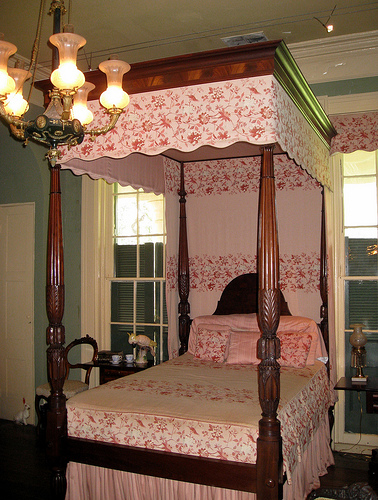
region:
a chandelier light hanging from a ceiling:
[0, 2, 140, 170]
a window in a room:
[340, 126, 373, 438]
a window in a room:
[99, 178, 172, 366]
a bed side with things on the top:
[91, 329, 160, 378]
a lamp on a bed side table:
[328, 319, 374, 398]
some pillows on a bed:
[194, 319, 309, 372]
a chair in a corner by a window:
[32, 325, 98, 434]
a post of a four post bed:
[246, 139, 286, 484]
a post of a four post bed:
[38, 156, 74, 492]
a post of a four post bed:
[174, 156, 195, 356]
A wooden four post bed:
[28, 35, 334, 497]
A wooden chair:
[31, 332, 99, 430]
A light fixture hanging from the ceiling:
[0, 1, 131, 168]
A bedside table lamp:
[347, 324, 370, 387]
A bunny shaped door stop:
[11, 395, 32, 430]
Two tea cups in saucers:
[107, 352, 136, 364]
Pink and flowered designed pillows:
[184, 312, 328, 368]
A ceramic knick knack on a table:
[127, 330, 158, 366]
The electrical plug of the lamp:
[338, 391, 375, 469]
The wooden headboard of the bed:
[215, 269, 299, 314]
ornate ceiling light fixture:
[3, 31, 128, 150]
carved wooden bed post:
[245, 135, 300, 499]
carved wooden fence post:
[43, 147, 78, 436]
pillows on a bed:
[190, 321, 309, 369]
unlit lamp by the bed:
[340, 310, 372, 391]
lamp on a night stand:
[342, 305, 372, 398]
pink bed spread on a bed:
[142, 367, 233, 445]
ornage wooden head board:
[218, 257, 288, 327]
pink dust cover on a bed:
[72, 465, 117, 497]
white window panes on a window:
[114, 198, 172, 347]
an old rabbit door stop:
[9, 392, 32, 437]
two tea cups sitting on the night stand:
[110, 348, 136, 372]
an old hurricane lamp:
[349, 318, 374, 389]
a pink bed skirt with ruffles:
[283, 419, 342, 497]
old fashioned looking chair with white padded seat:
[42, 326, 96, 419]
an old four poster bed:
[46, 145, 343, 492]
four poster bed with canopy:
[25, 55, 364, 375]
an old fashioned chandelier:
[5, 15, 130, 163]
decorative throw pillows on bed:
[195, 300, 308, 386]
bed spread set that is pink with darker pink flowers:
[56, 317, 334, 493]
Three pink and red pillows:
[190, 321, 313, 376]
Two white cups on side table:
[110, 347, 135, 366]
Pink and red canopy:
[35, 67, 339, 211]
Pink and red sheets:
[67, 332, 339, 474]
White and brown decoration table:
[34, 332, 105, 436]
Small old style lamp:
[340, 318, 370, 387]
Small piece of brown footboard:
[63, 432, 260, 498]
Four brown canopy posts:
[36, 140, 333, 440]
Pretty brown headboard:
[179, 264, 328, 374]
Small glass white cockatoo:
[125, 329, 164, 358]